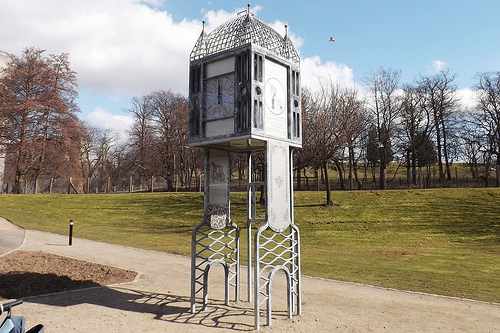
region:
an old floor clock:
[176, 2, 317, 321]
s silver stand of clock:
[173, 6, 315, 323]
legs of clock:
[179, 141, 311, 324]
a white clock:
[196, 64, 245, 126]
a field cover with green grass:
[52, 0, 499, 293]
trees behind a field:
[0, 37, 499, 188]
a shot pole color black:
[57, 213, 82, 249]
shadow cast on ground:
[5, 255, 187, 316]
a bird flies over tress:
[298, 8, 494, 123]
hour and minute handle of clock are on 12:
[198, 66, 240, 124]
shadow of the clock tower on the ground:
[3, 252, 265, 329]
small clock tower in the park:
[185, 10, 302, 324]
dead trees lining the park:
[5, 50, 497, 203]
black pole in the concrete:
[63, 215, 77, 247]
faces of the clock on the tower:
[195, 65, 290, 130]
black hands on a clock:
[210, 75, 228, 106]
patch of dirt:
[0, 243, 135, 306]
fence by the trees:
[4, 169, 494, 196]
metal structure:
[186, 3, 307, 321]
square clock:
[202, 77, 241, 119]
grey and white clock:
[164, 9, 342, 326]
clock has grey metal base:
[187, 165, 301, 332]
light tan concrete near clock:
[0, 195, 181, 328]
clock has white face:
[193, 72, 253, 122]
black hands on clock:
[209, 70, 244, 119]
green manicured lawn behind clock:
[107, 193, 471, 305]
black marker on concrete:
[66, 205, 86, 258]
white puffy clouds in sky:
[17, 9, 169, 99]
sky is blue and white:
[271, 4, 497, 88]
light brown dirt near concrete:
[0, 255, 122, 290]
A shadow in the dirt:
[65, 275, 142, 315]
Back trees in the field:
[322, 108, 496, 187]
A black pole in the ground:
[66, 218, 77, 245]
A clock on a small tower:
[200, 78, 237, 119]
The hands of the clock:
[208, 76, 226, 103]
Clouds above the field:
[80, 23, 167, 73]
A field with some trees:
[345, 195, 493, 287]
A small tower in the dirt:
[192, 15, 302, 324]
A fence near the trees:
[26, 177, 202, 190]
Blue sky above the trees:
[343, 22, 495, 69]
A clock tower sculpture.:
[187, 3, 303, 329]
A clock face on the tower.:
[200, 70, 237, 123]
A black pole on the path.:
[65, 216, 77, 248]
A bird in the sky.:
[325, 34, 336, 44]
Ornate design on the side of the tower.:
[268, 141, 290, 228]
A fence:
[1, 168, 498, 196]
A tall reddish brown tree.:
[0, 43, 91, 194]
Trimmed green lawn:
[340, 193, 496, 273]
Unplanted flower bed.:
[2, 248, 141, 306]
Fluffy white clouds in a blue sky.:
[2, 0, 496, 167]